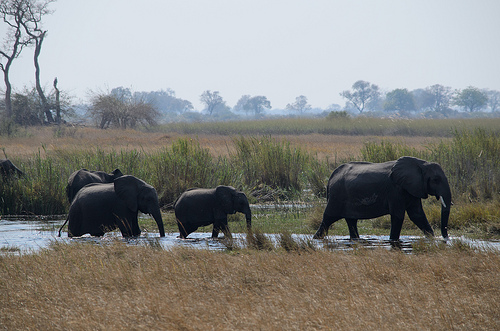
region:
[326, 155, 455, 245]
This elephant is walking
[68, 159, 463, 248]
this is a family of elephants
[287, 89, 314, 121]
this is a tree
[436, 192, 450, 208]
Elephant's tusk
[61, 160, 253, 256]
three elephants in the water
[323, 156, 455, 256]
a really big elephant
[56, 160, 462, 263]
4 elephants walking in water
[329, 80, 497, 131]
a bunch of trees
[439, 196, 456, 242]
an elephants trunk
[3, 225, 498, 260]
some water with grass growing around it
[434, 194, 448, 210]
The Tusk of the Largest Elephant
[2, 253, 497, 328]
A plain of natural wheat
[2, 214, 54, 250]
A portion of a small river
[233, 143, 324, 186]
Some tall grass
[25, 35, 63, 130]
A pair of tree trunks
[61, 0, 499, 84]
The Open Bright Sky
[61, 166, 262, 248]
A group of three young Elephants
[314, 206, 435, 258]
The legs of the Older Elephant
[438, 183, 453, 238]
The Trunk of the Older Elephant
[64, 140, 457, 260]
A Pack of Wild Elephants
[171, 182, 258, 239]
elephant in the water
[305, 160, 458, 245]
elephant in the water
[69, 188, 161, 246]
elephant in the water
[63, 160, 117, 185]
elephant in the water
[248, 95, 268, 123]
tree along the horizon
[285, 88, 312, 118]
tree along the horizon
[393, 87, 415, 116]
tree along the horizon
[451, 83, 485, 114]
tree along the horizon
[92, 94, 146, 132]
tree along the horizon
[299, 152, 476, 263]
This is an elephant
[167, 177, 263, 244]
This is an elephant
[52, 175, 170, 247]
This is an elephant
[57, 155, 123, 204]
This is an elephant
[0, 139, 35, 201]
This is an elephant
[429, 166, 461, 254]
This is a trunk of an elephant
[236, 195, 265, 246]
This is a trunk of an elephant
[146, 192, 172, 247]
This is a trunk of an elephant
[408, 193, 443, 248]
This is a leg of an elephant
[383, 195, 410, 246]
This is a leg of an elephant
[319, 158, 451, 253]
adult elephant in water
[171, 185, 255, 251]
baby elephant in marsh land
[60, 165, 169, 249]
two elephants in a marsh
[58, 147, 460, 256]
a group of elephants walking in a marsh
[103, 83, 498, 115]
a line of trees in the distance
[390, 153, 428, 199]
the ear of an elephant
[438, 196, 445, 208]
tusk of an elephant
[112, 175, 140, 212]
an elephant's ear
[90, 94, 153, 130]
a brown tree in the distance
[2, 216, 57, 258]
a pool of stagnant water